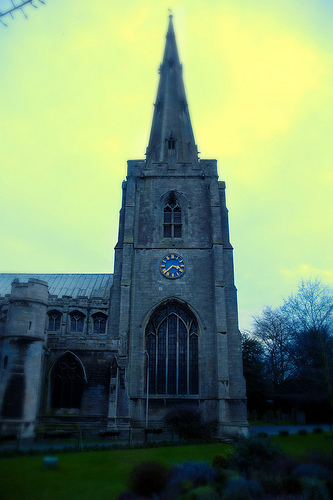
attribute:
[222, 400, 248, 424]
concrete block — large, on tower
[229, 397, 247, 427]
concrete block — large, on tower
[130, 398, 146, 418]
concrete block — large, on tower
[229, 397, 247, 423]
concrete block — on tower, large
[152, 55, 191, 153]
windows — small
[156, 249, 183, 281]
clock — blue faced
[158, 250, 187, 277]
roman numerals — gold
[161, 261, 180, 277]
hands — gold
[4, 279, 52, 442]
tower — short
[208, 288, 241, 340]
block — large, concrete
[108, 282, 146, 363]
block — concrete, large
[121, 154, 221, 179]
block — large, concrete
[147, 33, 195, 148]
spire — tall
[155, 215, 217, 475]
building — old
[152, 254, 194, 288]
clock — bright blue 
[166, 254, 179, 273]
numbers — gold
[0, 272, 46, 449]
tower —  round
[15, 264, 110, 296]
roof — peaked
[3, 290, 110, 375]
building — brick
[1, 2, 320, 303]
glow — yellow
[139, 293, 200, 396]
glass — stained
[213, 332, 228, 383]
block — large, concrete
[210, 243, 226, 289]
block — concrete, large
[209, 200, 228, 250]
block — concrete , large 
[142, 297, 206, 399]
windows — in front, arched , glass 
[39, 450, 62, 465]
item — blue 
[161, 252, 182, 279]
numbers — roman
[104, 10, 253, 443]
clock tower — tan 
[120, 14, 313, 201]
clouds — white 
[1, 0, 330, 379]
sky — blue 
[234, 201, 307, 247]
clouds — white 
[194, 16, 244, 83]
clouds — white 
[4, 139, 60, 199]
clouds — white 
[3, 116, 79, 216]
clouds — white 